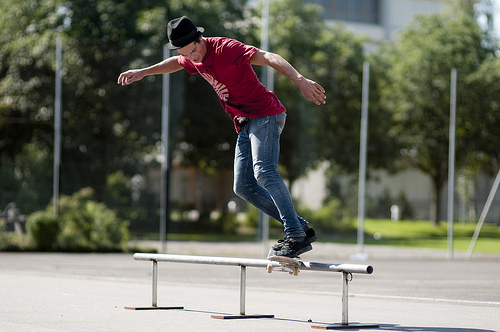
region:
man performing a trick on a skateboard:
[117, 16, 325, 273]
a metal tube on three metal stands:
[126, 251, 376, 329]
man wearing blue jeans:
[232, 111, 309, 239]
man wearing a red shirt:
[180, 35, 285, 131]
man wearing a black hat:
[162, 14, 205, 51]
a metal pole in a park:
[358, 58, 368, 259]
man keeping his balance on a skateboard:
[116, 16, 325, 273]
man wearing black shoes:
[275, 228, 317, 258]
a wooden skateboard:
[265, 255, 301, 275]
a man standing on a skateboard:
[116, 12, 326, 276]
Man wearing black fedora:
[115, 15, 332, 256]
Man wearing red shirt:
[114, 13, 328, 259]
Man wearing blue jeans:
[112, 13, 327, 258]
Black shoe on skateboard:
[274, 233, 313, 256]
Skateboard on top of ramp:
[265, 247, 302, 277]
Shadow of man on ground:
[330, 314, 499, 330]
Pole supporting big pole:
[149, 260, 159, 305]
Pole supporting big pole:
[237, 265, 247, 313]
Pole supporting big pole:
[340, 269, 350, 324]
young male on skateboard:
[115, 13, 330, 277]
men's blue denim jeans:
[225, 105, 325, 242]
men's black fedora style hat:
[160, 13, 207, 51]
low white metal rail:
[127, 245, 377, 330]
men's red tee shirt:
[172, 35, 289, 132]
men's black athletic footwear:
[268, 225, 318, 260]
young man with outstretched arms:
[111, 13, 333, 257]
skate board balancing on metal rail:
[263, 242, 303, 279]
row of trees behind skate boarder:
[3, 3, 498, 246]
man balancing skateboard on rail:
[115, 13, 335, 283]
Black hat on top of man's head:
[163, 15, 203, 52]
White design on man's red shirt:
[204, 69, 229, 103]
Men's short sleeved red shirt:
[176, 36, 285, 133]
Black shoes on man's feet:
[271, 223, 316, 258]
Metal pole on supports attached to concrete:
[123, 250, 380, 330]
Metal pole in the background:
[445, 65, 457, 262]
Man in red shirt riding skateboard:
[116, 15, 373, 276]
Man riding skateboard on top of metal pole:
[115, 15, 380, 330]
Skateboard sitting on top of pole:
[266, 243, 302, 275]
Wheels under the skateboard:
[266, 264, 298, 275]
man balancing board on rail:
[109, 12, 336, 274]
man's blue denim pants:
[224, 106, 314, 241]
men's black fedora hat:
[162, 14, 204, 52]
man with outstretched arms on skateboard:
[114, 10, 331, 281]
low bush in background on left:
[22, 187, 139, 264]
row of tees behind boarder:
[4, 3, 496, 238]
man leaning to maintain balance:
[114, 14, 329, 276]